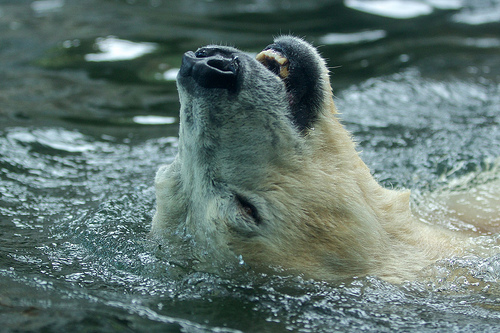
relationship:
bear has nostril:
[148, 31, 498, 291] [180, 48, 233, 82]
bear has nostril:
[148, 31, 498, 291] [182, 49, 214, 64]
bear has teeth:
[148, 31, 498, 291] [251, 43, 289, 67]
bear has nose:
[148, 31, 498, 291] [180, 48, 244, 98]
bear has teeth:
[148, 31, 498, 291] [256, 48, 288, 79]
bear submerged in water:
[148, 31, 498, 291] [35, 154, 181, 294]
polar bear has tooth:
[152, 36, 499, 300] [274, 65, 289, 82]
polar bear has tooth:
[152, 36, 499, 300] [261, 49, 283, 70]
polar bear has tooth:
[152, 36, 499, 300] [259, 45, 273, 58]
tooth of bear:
[255, 50, 265, 58] [150, 36, 467, 272]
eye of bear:
[230, 191, 257, 229] [148, 31, 498, 291]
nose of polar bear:
[180, 48, 244, 98] [152, 36, 499, 300]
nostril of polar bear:
[180, 48, 233, 82] [152, 36, 499, 300]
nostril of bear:
[180, 48, 233, 82] [148, 31, 498, 291]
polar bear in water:
[152, 36, 499, 300] [35, 154, 181, 294]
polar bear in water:
[152, 36, 499, 300] [4, 4, 496, 331]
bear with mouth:
[206, 40, 403, 246] [224, 32, 327, 128]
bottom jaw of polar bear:
[259, 33, 333, 139] [152, 36, 499, 300]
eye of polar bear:
[230, 191, 257, 229] [152, 36, 499, 300]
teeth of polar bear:
[256, 39, 311, 81] [152, 36, 499, 300]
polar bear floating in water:
[152, 36, 499, 300] [4, 4, 496, 331]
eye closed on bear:
[230, 191, 257, 229] [148, 31, 498, 291]